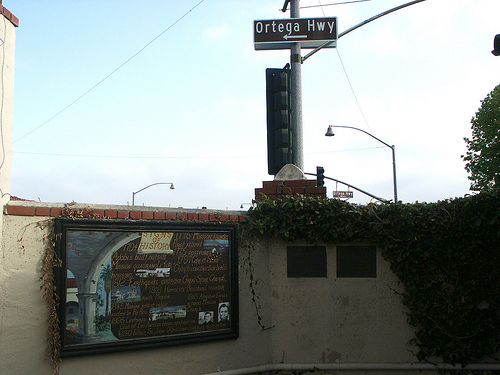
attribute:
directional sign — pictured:
[250, 15, 341, 43]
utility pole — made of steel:
[284, 4, 306, 170]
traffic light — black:
[266, 65, 297, 173]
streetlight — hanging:
[323, 116, 399, 203]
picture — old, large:
[47, 213, 242, 360]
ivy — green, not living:
[235, 184, 500, 369]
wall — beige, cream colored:
[1, 1, 497, 374]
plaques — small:
[283, 244, 380, 280]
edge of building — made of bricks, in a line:
[5, 201, 247, 228]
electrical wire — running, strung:
[4, 2, 219, 149]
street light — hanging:
[324, 121, 335, 146]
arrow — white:
[283, 31, 312, 43]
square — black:
[283, 244, 329, 280]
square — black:
[336, 242, 378, 279]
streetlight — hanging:
[167, 179, 176, 190]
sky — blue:
[3, 2, 498, 204]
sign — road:
[252, 13, 343, 54]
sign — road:
[251, 14, 341, 50]